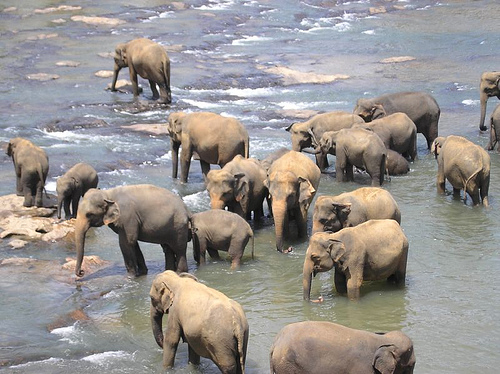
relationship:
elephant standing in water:
[109, 38, 172, 106] [0, 0, 496, 373]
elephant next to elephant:
[72, 183, 199, 279] [186, 209, 255, 271]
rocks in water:
[26, 54, 81, 85] [0, 0, 496, 373]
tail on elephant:
[249, 230, 257, 263] [186, 209, 255, 271]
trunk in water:
[302, 265, 325, 306] [0, 0, 496, 373]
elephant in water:
[186, 209, 255, 271] [0, 0, 496, 373]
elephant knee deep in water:
[298, 218, 410, 301] [0, 0, 496, 373]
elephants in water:
[3, 38, 498, 371] [0, 0, 496, 373]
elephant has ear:
[298, 218, 410, 301] [328, 238, 345, 262]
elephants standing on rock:
[4, 137, 102, 218] [1, 194, 78, 253]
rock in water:
[1, 194, 78, 253] [0, 0, 496, 373]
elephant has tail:
[429, 133, 492, 207] [462, 162, 484, 208]